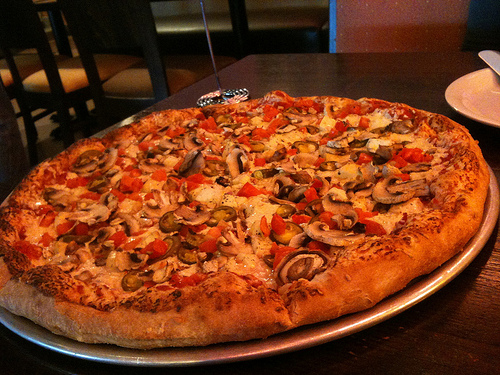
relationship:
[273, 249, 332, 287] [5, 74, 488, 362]
mushroom on pizza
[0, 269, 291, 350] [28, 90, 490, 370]
crust on pizza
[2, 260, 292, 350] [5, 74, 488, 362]
crust on pizza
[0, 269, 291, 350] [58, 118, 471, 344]
crust on pizza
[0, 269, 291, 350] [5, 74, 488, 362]
crust on pizza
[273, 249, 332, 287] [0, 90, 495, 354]
mushroom on pizza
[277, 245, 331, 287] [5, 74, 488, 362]
mushroom on pizza